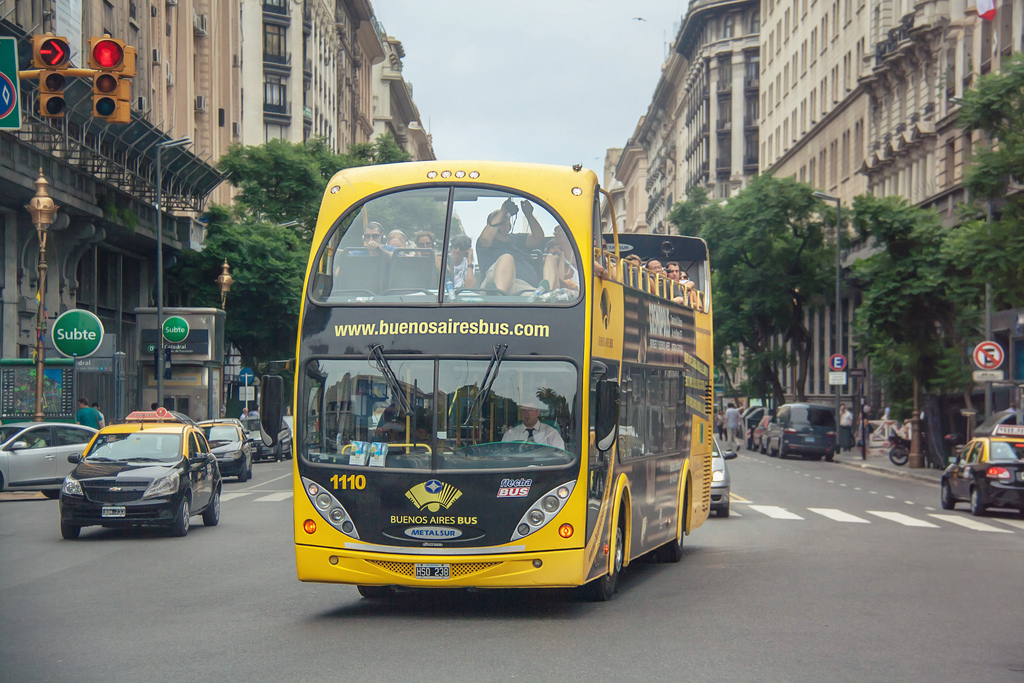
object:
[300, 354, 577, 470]
windshield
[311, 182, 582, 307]
windshield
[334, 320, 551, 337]
brand name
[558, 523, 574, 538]
headlight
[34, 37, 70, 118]
traffic lights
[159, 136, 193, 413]
street lights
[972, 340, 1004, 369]
street signs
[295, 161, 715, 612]
bus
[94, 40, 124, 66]
light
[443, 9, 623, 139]
sky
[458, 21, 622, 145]
clouds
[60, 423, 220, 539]
car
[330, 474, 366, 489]
number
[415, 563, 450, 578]
plate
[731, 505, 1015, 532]
crosswalk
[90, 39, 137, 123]
signal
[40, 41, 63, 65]
arrow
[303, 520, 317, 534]
headlight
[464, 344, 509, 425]
wiper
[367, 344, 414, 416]
wiper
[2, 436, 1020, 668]
street